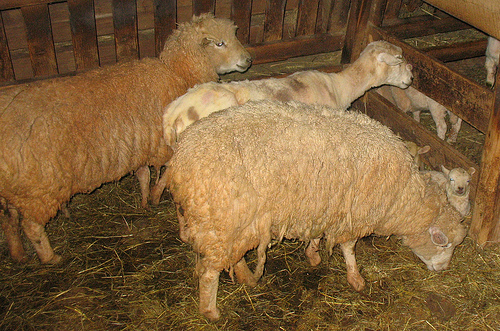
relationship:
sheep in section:
[162, 103, 472, 317] [2, 4, 492, 327]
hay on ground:
[8, 198, 493, 328] [6, 193, 498, 329]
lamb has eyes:
[157, 39, 416, 172] [392, 58, 406, 72]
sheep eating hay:
[162, 95, 472, 317] [0, 89, 498, 327]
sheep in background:
[162, 95, 472, 317] [1, 1, 498, 330]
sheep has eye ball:
[1, 5, 265, 268] [206, 31, 229, 51]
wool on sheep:
[158, 96, 471, 319] [162, 95, 472, 317]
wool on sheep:
[158, 96, 471, 319] [146, 91, 473, 327]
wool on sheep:
[0, 7, 269, 272] [1, 5, 265, 268]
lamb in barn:
[157, 25, 419, 174] [2, 2, 497, 330]